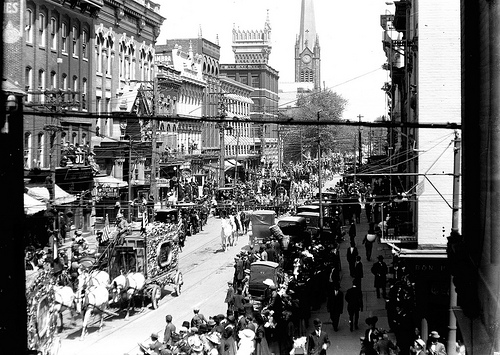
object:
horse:
[105, 269, 146, 321]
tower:
[295, 0, 321, 92]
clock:
[302, 54, 309, 62]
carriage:
[93, 223, 183, 310]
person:
[345, 240, 360, 276]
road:
[24, 169, 343, 354]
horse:
[69, 283, 110, 343]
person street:
[287, 208, 415, 352]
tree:
[296, 85, 346, 161]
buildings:
[32, 14, 318, 236]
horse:
[219, 218, 237, 253]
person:
[223, 280, 235, 314]